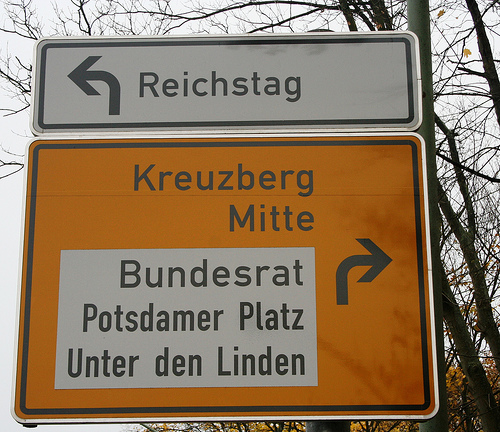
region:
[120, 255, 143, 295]
a letter is written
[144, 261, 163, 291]
a letter is written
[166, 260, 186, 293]
a letter is written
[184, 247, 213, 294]
a letter is written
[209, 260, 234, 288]
a letter is written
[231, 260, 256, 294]
a letter is written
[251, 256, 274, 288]
a letter is written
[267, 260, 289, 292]
a letter is written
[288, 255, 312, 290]
a letter is written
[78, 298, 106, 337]
a letter is written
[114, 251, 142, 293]
a letter written in black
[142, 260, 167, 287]
a letter written in black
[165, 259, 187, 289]
a letter written in black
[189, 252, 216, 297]
a letter written in black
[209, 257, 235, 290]
a letter written in black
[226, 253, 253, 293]
a letter written in black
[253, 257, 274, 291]
a letter written in black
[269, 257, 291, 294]
a letter written in black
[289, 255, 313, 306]
a letter written in black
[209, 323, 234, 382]
a letter written in black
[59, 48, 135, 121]
a black arrow on the sign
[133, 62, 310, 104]
black writing on a white sign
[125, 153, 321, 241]
black writing on a yellow sign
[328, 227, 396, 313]
black arrow on a yellow sign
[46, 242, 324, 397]
a white box on the yellow sign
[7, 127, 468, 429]
a yellow road sign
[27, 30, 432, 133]
a white road sign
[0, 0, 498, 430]
a gray sky overhead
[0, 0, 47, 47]
branches of a tree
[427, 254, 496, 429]
the trunk of a tree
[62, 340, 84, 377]
a letter written in black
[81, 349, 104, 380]
a letter written in black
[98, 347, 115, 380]
a letter written in black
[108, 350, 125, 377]
a letter written in black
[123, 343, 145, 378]
a letter written in black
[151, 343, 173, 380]
a letter written in black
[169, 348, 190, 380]
a letter written in black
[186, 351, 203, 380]
a letter written in black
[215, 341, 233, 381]
a letter written in black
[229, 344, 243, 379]
a letter written in black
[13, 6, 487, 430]
a german street sign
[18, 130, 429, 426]
a yellow white and black sign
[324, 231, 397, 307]
a black arrow pointing right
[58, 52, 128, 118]
a black arrow pointing left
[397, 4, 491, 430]
trees with no leaves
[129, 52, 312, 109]
a sign saying Reichstag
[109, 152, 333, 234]
a sign saying Kreuzberg Mitte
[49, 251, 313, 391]
a sign saying Bundesrat Potsdamer Platz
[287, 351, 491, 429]
trees with yellow leaves behind signs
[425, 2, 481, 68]
two leaves on empty trees